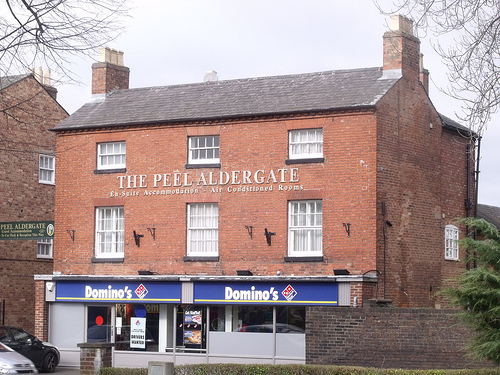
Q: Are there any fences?
A: No, there are no fences.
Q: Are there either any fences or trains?
A: No, there are no fences or trains.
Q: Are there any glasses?
A: No, there are no glasses.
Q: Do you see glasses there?
A: No, there are no glasses.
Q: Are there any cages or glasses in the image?
A: No, there are no glasses or cages.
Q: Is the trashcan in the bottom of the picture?
A: Yes, the trashcan is in the bottom of the image.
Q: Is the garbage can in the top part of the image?
A: No, the garbage can is in the bottom of the image.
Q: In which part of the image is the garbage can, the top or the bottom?
A: The garbage can is in the bottom of the image.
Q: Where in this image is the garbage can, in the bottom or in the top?
A: The garbage can is in the bottom of the image.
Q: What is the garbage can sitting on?
A: The garbage can is sitting on the sidewalk.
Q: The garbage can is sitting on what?
A: The garbage can is sitting on the sidewalk.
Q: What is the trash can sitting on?
A: The garbage can is sitting on the sidewalk.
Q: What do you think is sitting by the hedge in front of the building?
A: The trash bin is sitting by the hedge.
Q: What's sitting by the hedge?
A: The trash bin is sitting by the hedge.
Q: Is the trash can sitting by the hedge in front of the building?
A: Yes, the trash can is sitting by the hedge.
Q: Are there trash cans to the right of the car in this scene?
A: Yes, there is a trash can to the right of the car.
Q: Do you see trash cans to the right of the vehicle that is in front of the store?
A: Yes, there is a trash can to the right of the car.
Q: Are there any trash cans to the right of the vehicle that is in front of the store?
A: Yes, there is a trash can to the right of the car.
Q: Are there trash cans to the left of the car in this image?
A: No, the trash can is to the right of the car.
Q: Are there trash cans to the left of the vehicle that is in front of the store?
A: No, the trash can is to the right of the car.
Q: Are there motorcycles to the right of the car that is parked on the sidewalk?
A: No, there is a trash can to the right of the car.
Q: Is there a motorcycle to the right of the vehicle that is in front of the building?
A: No, there is a trash can to the right of the car.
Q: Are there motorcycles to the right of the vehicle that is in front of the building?
A: No, there is a trash can to the right of the car.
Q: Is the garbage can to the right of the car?
A: Yes, the garbage can is to the right of the car.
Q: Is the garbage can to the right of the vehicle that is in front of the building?
A: Yes, the garbage can is to the right of the car.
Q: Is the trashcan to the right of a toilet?
A: No, the trashcan is to the right of the car.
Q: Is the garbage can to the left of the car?
A: No, the garbage can is to the right of the car.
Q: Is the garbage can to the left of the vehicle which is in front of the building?
A: No, the garbage can is to the right of the car.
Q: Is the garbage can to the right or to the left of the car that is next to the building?
A: The garbage can is to the right of the car.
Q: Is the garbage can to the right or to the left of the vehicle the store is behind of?
A: The garbage can is to the right of the car.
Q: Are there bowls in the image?
A: No, there are no bowls.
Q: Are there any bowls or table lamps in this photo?
A: No, there are no bowls or table lamps.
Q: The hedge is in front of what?
A: The hedge is in front of the building.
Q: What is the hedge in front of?
A: The hedge is in front of the building.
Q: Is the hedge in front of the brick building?
A: Yes, the hedge is in front of the building.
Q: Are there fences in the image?
A: No, there are no fences.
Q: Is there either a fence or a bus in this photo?
A: No, there are no fences or buses.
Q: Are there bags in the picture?
A: No, there are no bags.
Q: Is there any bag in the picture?
A: No, there are no bags.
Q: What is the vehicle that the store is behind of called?
A: The vehicle is a car.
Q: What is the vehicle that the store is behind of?
A: The vehicle is a car.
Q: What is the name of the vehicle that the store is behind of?
A: The vehicle is a car.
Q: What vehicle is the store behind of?
A: The store is behind the car.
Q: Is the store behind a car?
A: Yes, the store is behind a car.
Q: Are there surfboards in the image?
A: No, there are no surfboards.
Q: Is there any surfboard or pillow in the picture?
A: No, there are no surfboards or pillows.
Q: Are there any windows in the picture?
A: Yes, there is a window.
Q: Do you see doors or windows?
A: Yes, there is a window.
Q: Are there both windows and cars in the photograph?
A: Yes, there are both a window and a car.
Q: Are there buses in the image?
A: No, there are no buses.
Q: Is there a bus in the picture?
A: No, there are no buses.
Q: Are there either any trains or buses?
A: No, there are no buses or trains.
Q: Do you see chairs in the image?
A: No, there are no chairs.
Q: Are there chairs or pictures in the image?
A: No, there are no chairs or pictures.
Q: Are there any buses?
A: No, there are no buses.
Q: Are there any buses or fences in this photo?
A: No, there are no buses or fences.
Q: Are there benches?
A: No, there are no benches.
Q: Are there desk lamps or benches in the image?
A: No, there are no benches or desk lamps.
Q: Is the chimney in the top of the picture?
A: Yes, the chimney is in the top of the image.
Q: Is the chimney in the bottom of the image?
A: No, the chimney is in the top of the image.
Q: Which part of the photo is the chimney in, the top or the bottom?
A: The chimney is in the top of the image.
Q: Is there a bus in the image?
A: No, there are no buses.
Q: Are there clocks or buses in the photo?
A: No, there are no buses or clocks.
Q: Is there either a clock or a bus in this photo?
A: No, there are no buses or clocks.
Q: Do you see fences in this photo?
A: No, there are no fences.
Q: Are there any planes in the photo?
A: No, there are no planes.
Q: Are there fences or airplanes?
A: No, there are no airplanes or fences.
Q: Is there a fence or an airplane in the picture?
A: No, there are no airplanes or fences.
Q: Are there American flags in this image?
A: No, there are no American flags.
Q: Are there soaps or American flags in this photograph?
A: No, there are no American flags or soaps.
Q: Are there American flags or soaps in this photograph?
A: No, there are no American flags or soaps.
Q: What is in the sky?
A: The clouds are in the sky.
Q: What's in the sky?
A: The clouds are in the sky.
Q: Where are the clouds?
A: The clouds are in the sky.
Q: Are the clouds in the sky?
A: Yes, the clouds are in the sky.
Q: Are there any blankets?
A: No, there are no blankets.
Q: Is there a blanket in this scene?
A: No, there are no blankets.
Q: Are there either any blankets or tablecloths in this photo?
A: No, there are no blankets or tablecloths.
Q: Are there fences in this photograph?
A: No, there are no fences.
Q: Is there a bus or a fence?
A: No, there are no fences or buses.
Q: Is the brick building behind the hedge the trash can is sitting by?
A: Yes, the building is behind the hedge.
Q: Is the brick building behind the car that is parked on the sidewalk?
A: Yes, the building is behind the car.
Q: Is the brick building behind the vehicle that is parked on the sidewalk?
A: Yes, the building is behind the car.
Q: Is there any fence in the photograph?
A: No, there are no fences.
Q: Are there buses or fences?
A: No, there are no fences or buses.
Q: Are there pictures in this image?
A: No, there are no pictures.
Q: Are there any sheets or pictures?
A: No, there are no pictures or sheets.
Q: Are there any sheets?
A: No, there are no sheets.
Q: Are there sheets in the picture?
A: No, there are no sheets.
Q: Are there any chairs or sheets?
A: No, there are no sheets or chairs.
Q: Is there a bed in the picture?
A: No, there are no beds.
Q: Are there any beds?
A: No, there are no beds.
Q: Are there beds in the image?
A: No, there are no beds.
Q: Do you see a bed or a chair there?
A: No, there are no beds or chairs.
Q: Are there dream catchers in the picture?
A: No, there are no dream catchers.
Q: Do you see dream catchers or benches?
A: No, there are no dream catchers or benches.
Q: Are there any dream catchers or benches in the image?
A: No, there are no dream catchers or benches.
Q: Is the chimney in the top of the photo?
A: Yes, the chimney is in the top of the image.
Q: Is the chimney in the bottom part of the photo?
A: No, the chimney is in the top of the image.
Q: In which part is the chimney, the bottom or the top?
A: The chimney is in the top of the image.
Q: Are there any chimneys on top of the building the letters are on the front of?
A: Yes, there is a chimney on top of the building.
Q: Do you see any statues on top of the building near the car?
A: No, there is a chimney on top of the building.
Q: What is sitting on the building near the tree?
A: The chimney is sitting on the building.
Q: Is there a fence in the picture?
A: No, there are no fences.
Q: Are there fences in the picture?
A: No, there are no fences.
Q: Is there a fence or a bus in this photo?
A: No, there are no fences or buses.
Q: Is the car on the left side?
A: Yes, the car is on the left of the image.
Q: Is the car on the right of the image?
A: No, the car is on the left of the image.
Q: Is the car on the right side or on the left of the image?
A: The car is on the left of the image.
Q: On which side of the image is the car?
A: The car is on the left of the image.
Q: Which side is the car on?
A: The car is on the left of the image.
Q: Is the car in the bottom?
A: Yes, the car is in the bottom of the image.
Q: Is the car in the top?
A: No, the car is in the bottom of the image.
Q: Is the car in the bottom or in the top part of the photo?
A: The car is in the bottom of the image.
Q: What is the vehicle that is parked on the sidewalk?
A: The vehicle is a car.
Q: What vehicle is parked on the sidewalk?
A: The vehicle is a car.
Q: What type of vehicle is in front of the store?
A: The vehicle is a car.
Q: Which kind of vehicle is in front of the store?
A: The vehicle is a car.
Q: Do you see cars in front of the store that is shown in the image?
A: Yes, there is a car in front of the store.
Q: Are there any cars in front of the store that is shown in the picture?
A: Yes, there is a car in front of the store.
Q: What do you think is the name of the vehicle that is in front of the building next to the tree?
A: The vehicle is a car.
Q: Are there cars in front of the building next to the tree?
A: Yes, there is a car in front of the building.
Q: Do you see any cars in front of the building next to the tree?
A: Yes, there is a car in front of the building.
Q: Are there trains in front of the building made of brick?
A: No, there is a car in front of the building.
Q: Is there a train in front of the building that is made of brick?
A: No, there is a car in front of the building.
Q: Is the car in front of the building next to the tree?
A: Yes, the car is in front of the building.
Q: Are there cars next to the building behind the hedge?
A: Yes, there is a car next to the building.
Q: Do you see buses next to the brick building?
A: No, there is a car next to the building.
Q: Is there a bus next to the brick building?
A: No, there is a car next to the building.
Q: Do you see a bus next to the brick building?
A: No, there is a car next to the building.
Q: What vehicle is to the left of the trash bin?
A: The vehicle is a car.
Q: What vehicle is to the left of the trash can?
A: The vehicle is a car.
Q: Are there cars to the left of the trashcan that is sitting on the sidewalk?
A: Yes, there is a car to the left of the garbage can.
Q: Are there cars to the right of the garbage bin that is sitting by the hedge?
A: No, the car is to the left of the trash can.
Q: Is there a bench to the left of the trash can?
A: No, there is a car to the left of the trash can.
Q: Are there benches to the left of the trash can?
A: No, there is a car to the left of the trash can.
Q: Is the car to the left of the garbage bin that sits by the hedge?
A: Yes, the car is to the left of the garbage can.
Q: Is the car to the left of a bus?
A: No, the car is to the left of the garbage can.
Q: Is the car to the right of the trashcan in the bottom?
A: No, the car is to the left of the garbage can.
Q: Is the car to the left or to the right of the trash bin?
A: The car is to the left of the trash bin.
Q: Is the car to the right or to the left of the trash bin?
A: The car is to the left of the trash bin.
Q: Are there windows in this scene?
A: Yes, there is a window.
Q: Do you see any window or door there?
A: Yes, there is a window.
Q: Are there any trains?
A: No, there are no trains.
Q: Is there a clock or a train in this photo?
A: No, there are no trains or clocks.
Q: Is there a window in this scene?
A: Yes, there is a window.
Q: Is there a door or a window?
A: Yes, there is a window.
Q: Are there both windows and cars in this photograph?
A: Yes, there are both a window and a car.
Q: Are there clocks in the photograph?
A: No, there are no clocks.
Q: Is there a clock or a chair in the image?
A: No, there are no clocks or chairs.